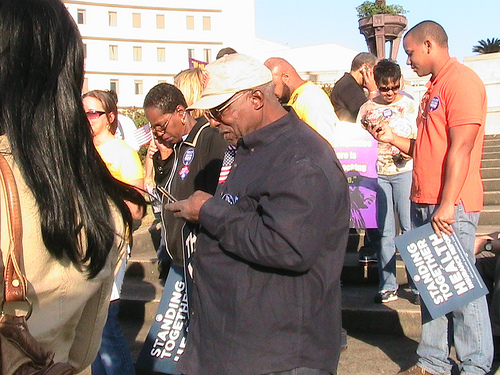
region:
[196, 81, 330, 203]
A old man.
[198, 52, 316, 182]
A man in a white hat.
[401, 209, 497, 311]
This is a blue book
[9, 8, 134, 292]
a women with black hair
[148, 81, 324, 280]
A man playing with phone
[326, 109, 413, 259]
A purple poster in background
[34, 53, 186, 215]
a women in purple glasses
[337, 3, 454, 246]
A statute in background.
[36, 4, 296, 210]
A tall white building in background.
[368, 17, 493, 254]
a man in red shirt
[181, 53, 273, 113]
White cap on a mans head.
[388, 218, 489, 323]
Blue sign with white writing a man in orange is holding.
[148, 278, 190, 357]
The word STANDING on a blue sign a colored man is holding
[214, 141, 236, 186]
Part of an American Flag.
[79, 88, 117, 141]
A woman's head that has sunglasses on and brown hair.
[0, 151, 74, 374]
Brown strap and purse on a black haired woman's shoulder.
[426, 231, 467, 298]
The word HEALTH on a blue sign a man in orange is wearing.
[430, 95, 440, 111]
A blue button on a man wearing oranges shirt.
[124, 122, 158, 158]
Small American flag beside a black woman's head.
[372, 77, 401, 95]
Dark sunglasses on a black woman's face to the right.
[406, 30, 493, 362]
person holding a sign.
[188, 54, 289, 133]
hat on a person.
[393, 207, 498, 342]
a blue sign with words.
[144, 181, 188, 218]
phone in someones hand.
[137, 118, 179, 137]
glasses on someones head.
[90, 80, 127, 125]
hair on someones head.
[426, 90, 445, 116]
sticker on someones chest.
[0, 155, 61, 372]
purse on a persons shoulder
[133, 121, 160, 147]
the american flag.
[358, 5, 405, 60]
item holding a plant.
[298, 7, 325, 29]
part of the sky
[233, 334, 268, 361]
part of a shirt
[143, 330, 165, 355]
part of a poster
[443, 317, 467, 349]
part of a jeans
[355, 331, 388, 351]
part of a shadow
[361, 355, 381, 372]
part of the floor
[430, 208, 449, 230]
part of a hand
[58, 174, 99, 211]
part of a hair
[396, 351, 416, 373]
part of a shoe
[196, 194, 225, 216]
part of a sleeve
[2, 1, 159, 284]
long black hair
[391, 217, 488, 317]
small poster with a political slogan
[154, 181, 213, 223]
hand holding a cell phone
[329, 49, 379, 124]
man using a cell phone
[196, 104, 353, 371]
long sleeved navy blue shirt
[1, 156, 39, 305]
leather handle of shoulder bag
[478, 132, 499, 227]
flight of concrete stairs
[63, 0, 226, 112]
white building with windows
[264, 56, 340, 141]
bald man with a beard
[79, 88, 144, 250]
woman wearing sunglasses